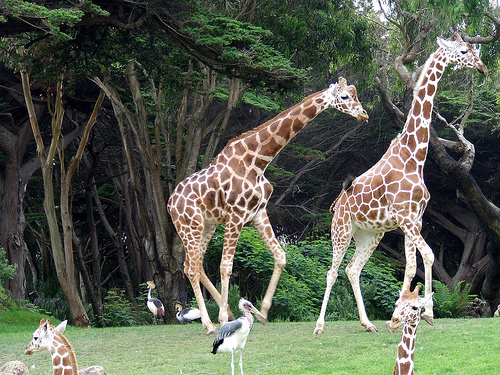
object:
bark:
[453, 165, 468, 181]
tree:
[350, 0, 497, 318]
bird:
[211, 295, 266, 375]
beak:
[250, 307, 263, 322]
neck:
[49, 337, 80, 374]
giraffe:
[164, 73, 368, 331]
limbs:
[21, 73, 47, 158]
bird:
[141, 281, 167, 322]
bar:
[23, 76, 94, 327]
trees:
[128, 0, 309, 325]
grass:
[0, 313, 499, 374]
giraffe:
[312, 30, 492, 335]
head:
[382, 280, 432, 327]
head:
[319, 76, 369, 124]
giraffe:
[382, 284, 437, 374]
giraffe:
[311, 23, 486, 336]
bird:
[174, 296, 203, 327]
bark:
[158, 245, 173, 263]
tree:
[0, 0, 309, 327]